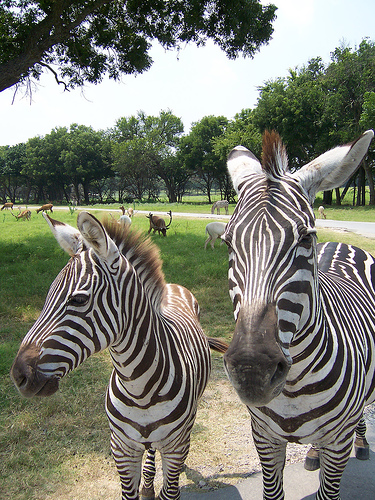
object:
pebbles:
[191, 443, 309, 491]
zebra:
[215, 114, 374, 499]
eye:
[296, 225, 317, 252]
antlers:
[145, 212, 150, 220]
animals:
[144, 210, 174, 238]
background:
[2, 1, 375, 496]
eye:
[68, 291, 92, 307]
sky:
[1, 2, 375, 153]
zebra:
[8, 205, 229, 500]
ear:
[73, 210, 108, 253]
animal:
[36, 201, 56, 218]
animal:
[9, 206, 33, 222]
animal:
[1, 201, 13, 210]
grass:
[1, 206, 225, 480]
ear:
[224, 139, 266, 193]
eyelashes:
[67, 291, 90, 299]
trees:
[226, 40, 375, 205]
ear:
[290, 127, 373, 197]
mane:
[102, 216, 167, 310]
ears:
[45, 211, 83, 257]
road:
[318, 211, 373, 236]